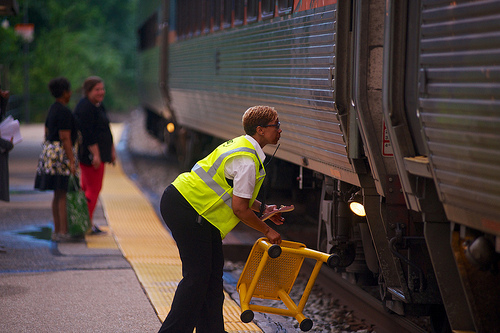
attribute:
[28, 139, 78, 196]
skirt — patterned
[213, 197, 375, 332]
stool — yellow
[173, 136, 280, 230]
vest — yellow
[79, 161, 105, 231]
pants — red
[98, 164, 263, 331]
yellow pavement — textured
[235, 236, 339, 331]
stool — yellow, metal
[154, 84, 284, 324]
woman — framed 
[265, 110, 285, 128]
glasses — dark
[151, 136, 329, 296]
vest — yellow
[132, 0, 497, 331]
train — silver, passenger, parked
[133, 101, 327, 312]
woman — crouching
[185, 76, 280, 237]
vest — yellow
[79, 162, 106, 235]
pants — red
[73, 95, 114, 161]
sweater — blue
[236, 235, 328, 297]
stepstool — yellow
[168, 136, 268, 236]
vest — yellow, gray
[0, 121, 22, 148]
paper — white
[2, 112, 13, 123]
paper — white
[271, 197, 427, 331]
tracks — train 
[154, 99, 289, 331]
woman — holding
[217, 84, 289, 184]
hair — short, brown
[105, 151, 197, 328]
line — yellow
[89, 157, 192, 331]
stripe — yellow, painted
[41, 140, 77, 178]
skirt — white , black  , patterned 